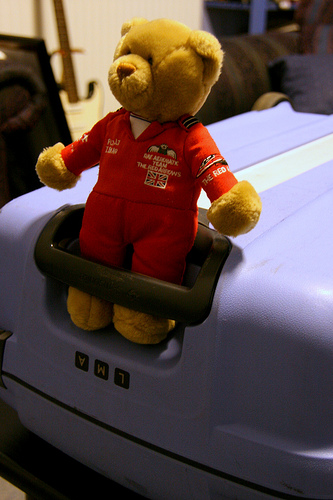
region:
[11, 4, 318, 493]
a teddy bear on a piece of luggage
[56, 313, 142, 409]
the letters LMA on the suitcase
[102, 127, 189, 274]
the bear is wearing a red outfit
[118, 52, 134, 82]
the bears nose is brown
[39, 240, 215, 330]
the luggage handle bar is black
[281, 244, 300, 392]
the luggage is voilet in color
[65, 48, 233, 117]
the bear has two ears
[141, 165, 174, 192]
the bear has a british logo on it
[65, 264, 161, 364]
the bear has two legs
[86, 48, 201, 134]
the bear has a furry head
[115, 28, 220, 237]
A teddy bear attached to luggage.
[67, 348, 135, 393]
Three black letters on the suitcase.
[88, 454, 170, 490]
Scratches and marks on the suitcase.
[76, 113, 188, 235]
The teddy is wearing red overalls.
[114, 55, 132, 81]
The bear nose is brown.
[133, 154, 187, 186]
A confederate flag on the teddy bear.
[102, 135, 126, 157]
White writing on the bear overall.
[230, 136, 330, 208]
A white stripe on the suitcase.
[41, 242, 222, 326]
The handle of the suitcase is black.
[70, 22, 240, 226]
The teddy bear is brown.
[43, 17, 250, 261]
the bear is brown in colour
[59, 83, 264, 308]
it has a red outfit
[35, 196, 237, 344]
the bags handle is black in colour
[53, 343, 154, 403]
the bag has some buttons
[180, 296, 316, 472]
the bag is made of plastic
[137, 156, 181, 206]
a flag is on the outfit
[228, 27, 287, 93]
the sofa is brown in colour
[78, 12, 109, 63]
the wall is white in colour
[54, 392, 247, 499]
the bag has a black stripe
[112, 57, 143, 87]
the nose is brown in colour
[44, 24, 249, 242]
this is a doll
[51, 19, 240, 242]
the doll is brown in color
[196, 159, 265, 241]
this is a hand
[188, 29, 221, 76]
this is an ear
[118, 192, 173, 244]
the clothe is red in color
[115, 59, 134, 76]
this is a nose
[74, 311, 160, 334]
these are the legs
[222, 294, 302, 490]
this is a suitcase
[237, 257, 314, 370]
the suitcase is white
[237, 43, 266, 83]
this is a sofa